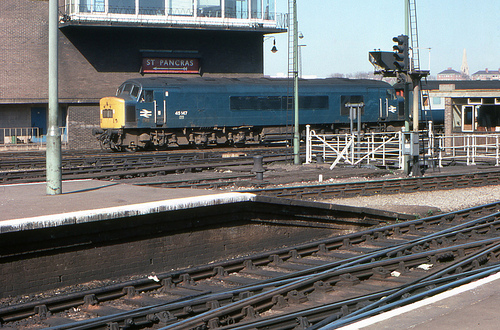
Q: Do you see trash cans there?
A: No, there are no trash cans.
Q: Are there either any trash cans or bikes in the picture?
A: No, there are no trash cans or bikes.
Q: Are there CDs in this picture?
A: No, there are no cds.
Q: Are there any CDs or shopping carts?
A: No, there are no CDs or shopping carts.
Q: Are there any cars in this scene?
A: No, there are no cars.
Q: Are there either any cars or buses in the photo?
A: No, there are no cars or buses.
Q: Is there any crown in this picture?
A: No, there are no crowns.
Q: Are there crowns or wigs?
A: No, there are no crowns or wigs.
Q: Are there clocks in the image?
A: No, there are no clocks.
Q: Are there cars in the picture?
A: No, there are no cars.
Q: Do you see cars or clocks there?
A: No, there are no cars or clocks.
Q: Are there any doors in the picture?
A: Yes, there is a door.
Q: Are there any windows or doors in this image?
A: Yes, there is a door.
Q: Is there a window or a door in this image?
A: Yes, there is a door.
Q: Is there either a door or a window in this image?
A: Yes, there is a door.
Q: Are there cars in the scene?
A: No, there are no cars.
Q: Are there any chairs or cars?
A: No, there are no cars or chairs.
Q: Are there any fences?
A: Yes, there is a fence.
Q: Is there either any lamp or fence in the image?
A: Yes, there is a fence.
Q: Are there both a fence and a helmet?
A: No, there is a fence but no helmets.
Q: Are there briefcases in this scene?
A: No, there are no briefcases.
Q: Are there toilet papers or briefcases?
A: No, there are no briefcases or toilet papers.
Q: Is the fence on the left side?
A: No, the fence is on the right of the image.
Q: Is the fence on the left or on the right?
A: The fence is on the right of the image.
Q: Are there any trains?
A: Yes, there is a train.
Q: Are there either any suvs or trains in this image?
A: Yes, there is a train.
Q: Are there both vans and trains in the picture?
A: No, there is a train but no vans.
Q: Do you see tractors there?
A: No, there are no tractors.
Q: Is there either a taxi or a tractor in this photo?
A: No, there are no tractors or taxis.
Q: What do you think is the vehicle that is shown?
A: The vehicle is a train.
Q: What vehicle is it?
A: The vehicle is a train.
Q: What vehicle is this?
A: That is a train.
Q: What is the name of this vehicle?
A: That is a train.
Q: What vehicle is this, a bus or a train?
A: That is a train.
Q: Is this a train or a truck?
A: This is a train.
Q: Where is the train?
A: The train is at the building.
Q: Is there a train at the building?
A: Yes, there is a train at the building.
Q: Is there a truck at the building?
A: No, there is a train at the building.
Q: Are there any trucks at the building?
A: No, there is a train at the building.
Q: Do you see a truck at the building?
A: No, there is a train at the building.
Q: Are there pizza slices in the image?
A: No, there are no pizza slices.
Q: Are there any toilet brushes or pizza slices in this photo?
A: No, there are no pizza slices or toilet brushes.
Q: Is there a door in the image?
A: Yes, there is a door.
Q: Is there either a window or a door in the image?
A: Yes, there is a door.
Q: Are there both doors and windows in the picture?
A: Yes, there are both a door and a window.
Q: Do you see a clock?
A: No, there are no clocks.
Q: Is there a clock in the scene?
A: No, there are no clocks.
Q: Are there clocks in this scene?
A: No, there are no clocks.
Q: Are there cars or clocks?
A: No, there are no clocks or cars.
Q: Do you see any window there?
A: Yes, there are windows.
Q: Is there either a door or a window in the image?
A: Yes, there are windows.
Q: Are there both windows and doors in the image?
A: Yes, there are both windows and a door.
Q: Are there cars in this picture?
A: No, there are no cars.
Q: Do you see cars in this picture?
A: No, there are no cars.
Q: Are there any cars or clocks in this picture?
A: No, there are no cars or clocks.